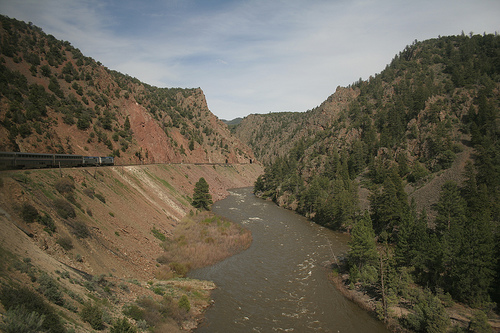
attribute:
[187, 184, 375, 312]
water — gray, murky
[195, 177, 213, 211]
shrubbery — green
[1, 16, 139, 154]
trees — green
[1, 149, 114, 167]
train — white, long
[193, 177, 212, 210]
tree — green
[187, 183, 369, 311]
river — running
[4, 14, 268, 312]
canyon — sloped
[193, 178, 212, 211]
shrubs — growing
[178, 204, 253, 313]
bank — flat